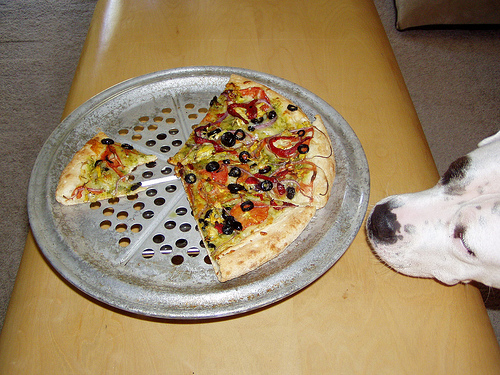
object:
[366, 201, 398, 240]
nose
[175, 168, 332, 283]
pieces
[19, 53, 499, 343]
close-up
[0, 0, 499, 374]
surface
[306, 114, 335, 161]
crust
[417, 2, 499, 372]
right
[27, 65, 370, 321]
pan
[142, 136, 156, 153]
whole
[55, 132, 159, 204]
pizza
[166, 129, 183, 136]
whole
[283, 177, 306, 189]
onions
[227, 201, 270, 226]
tomato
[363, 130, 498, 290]
head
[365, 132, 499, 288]
dog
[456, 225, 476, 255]
eyes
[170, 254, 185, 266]
holes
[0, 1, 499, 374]
table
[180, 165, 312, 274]
pizza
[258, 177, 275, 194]
olives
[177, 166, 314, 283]
pizza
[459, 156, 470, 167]
fur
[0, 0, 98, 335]
carpet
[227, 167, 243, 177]
topping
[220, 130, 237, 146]
topping